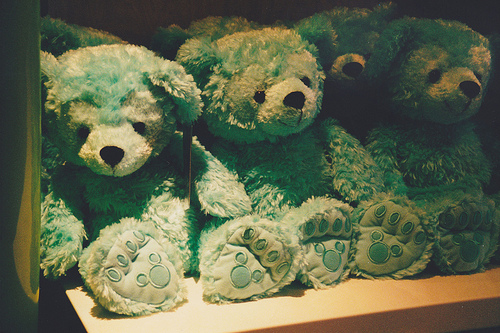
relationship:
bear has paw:
[39, 45, 301, 310] [211, 222, 292, 299]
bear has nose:
[39, 45, 301, 310] [99, 144, 124, 166]